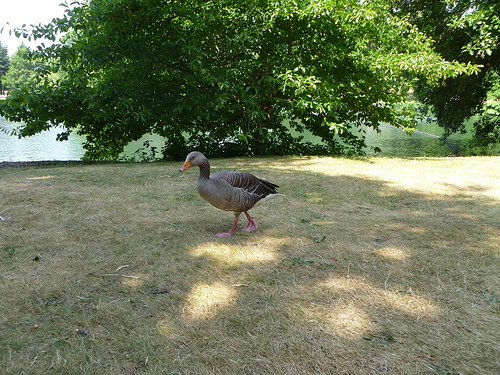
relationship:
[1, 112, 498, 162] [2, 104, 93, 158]
river with sunlight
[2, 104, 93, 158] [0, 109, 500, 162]
sunlight reflecting off river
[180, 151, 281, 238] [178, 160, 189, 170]
duck with beak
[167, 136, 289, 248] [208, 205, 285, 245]
duck with feet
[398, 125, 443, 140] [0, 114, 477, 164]
gray stick in water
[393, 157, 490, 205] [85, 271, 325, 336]
sunshine shows on ground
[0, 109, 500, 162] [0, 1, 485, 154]
river behind brown tree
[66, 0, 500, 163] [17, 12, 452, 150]
green leaves on bush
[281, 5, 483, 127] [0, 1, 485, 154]
sunshine area on brown tree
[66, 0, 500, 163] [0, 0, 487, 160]
green leaves on tree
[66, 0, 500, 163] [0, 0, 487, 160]
green leaves in tree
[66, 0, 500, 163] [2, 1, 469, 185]
green leaves in tree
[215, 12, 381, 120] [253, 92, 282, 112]
green leaves in brown tree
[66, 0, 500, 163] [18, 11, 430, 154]
green leaves on tree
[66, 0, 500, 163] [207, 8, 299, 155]
green leaves on tree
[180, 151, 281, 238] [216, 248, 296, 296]
duck walking on grass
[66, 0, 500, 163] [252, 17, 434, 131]
green leaves on tree